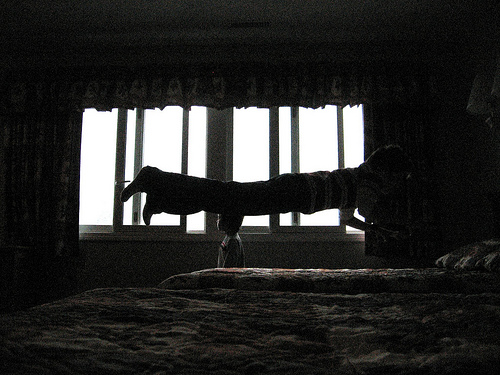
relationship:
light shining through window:
[90, 130, 110, 175] [86, 111, 359, 169]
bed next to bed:
[31, 291, 493, 368] [175, 256, 499, 289]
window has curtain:
[86, 111, 359, 169] [5, 118, 73, 294]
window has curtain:
[86, 111, 359, 169] [363, 111, 422, 143]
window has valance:
[86, 111, 359, 169] [7, 70, 449, 112]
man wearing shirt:
[109, 138, 420, 241] [307, 172, 373, 209]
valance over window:
[7, 70, 449, 112] [86, 111, 359, 169]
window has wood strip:
[86, 111, 359, 169] [266, 112, 279, 174]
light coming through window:
[301, 121, 333, 167] [86, 111, 359, 169]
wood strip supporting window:
[180, 112, 192, 173] [86, 111, 359, 169]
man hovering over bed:
[109, 138, 420, 241] [31, 291, 493, 368]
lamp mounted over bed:
[462, 76, 499, 126] [175, 256, 499, 289]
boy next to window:
[218, 217, 248, 264] [86, 111, 359, 169]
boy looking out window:
[218, 217, 248, 264] [86, 111, 359, 169]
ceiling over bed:
[7, 1, 494, 32] [175, 256, 499, 289]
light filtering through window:
[90, 130, 110, 175] [86, 111, 359, 169]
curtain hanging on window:
[5, 118, 73, 294] [86, 111, 359, 169]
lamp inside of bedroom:
[462, 76, 499, 126] [13, 13, 487, 368]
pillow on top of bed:
[443, 241, 499, 267] [175, 256, 499, 289]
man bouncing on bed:
[109, 138, 420, 241] [31, 291, 493, 368]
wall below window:
[80, 244, 215, 273] [86, 111, 359, 169]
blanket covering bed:
[55, 310, 466, 352] [31, 291, 493, 368]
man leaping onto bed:
[109, 138, 420, 241] [31, 291, 493, 368]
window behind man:
[86, 111, 359, 169] [109, 138, 420, 241]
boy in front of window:
[218, 217, 248, 264] [86, 111, 359, 169]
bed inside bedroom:
[31, 291, 493, 368] [13, 13, 487, 368]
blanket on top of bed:
[55, 310, 466, 352] [31, 291, 493, 368]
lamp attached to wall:
[462, 76, 499, 126] [80, 244, 215, 273]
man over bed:
[109, 138, 420, 241] [31, 291, 493, 368]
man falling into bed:
[109, 138, 420, 241] [31, 291, 493, 368]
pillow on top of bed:
[443, 241, 499, 267] [31, 291, 493, 368]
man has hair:
[109, 138, 420, 241] [376, 147, 405, 166]